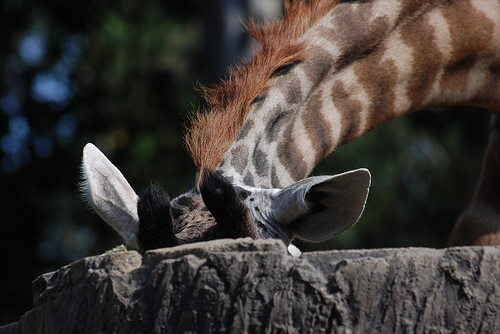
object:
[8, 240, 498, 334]
wood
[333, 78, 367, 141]
spot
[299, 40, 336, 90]
spot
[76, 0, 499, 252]
giraffe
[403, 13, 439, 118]
spot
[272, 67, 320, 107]
spot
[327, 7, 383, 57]
spot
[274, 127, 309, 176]
spot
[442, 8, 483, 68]
spot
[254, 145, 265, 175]
spot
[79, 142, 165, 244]
ear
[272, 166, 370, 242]
ear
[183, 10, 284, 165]
mane